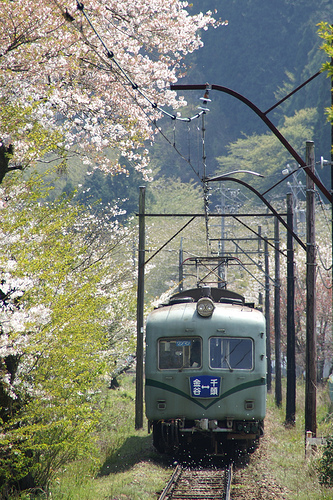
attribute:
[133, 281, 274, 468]
train — green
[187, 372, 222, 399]
sign — blue , white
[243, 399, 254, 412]
light — head light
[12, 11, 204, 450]
tree — white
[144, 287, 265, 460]
car — train car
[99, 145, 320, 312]
poles — utility poles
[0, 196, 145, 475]
bushes — Green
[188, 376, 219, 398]
sticker — blue, white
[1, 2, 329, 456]
cherry blossoms — Pink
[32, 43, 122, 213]
shrub — green, small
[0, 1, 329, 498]
flowers — white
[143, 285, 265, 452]
train — green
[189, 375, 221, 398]
symbol — asian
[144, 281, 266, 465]
train — green